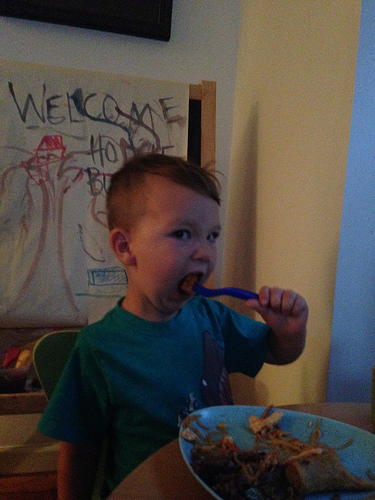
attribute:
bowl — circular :
[166, 378, 374, 492]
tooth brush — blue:
[183, 276, 262, 312]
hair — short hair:
[157, 154, 226, 205]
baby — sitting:
[34, 150, 310, 498]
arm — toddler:
[249, 279, 321, 366]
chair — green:
[31, 322, 110, 498]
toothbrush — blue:
[173, 272, 252, 303]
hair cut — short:
[105, 151, 227, 232]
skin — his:
[137, 234, 158, 281]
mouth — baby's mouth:
[136, 252, 227, 307]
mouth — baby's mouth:
[132, 262, 220, 311]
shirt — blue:
[35, 293, 270, 485]